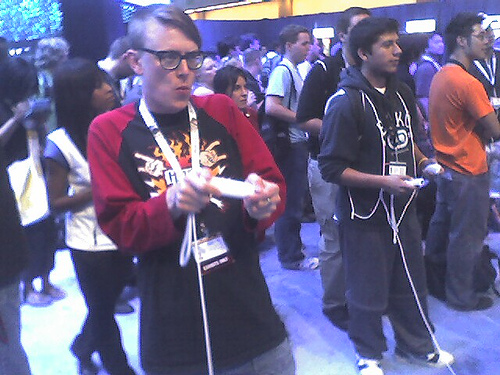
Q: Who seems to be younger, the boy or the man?
A: The boy is younger than the man.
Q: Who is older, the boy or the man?
A: The man is older than the boy.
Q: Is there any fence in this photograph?
A: No, there are no fences.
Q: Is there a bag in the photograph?
A: Yes, there is a bag.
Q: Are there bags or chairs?
A: Yes, there is a bag.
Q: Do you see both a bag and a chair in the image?
A: No, there is a bag but no chairs.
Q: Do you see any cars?
A: No, there are no cars.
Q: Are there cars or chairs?
A: No, there are no cars or chairs.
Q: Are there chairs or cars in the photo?
A: No, there are no cars or chairs.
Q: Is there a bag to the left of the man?
A: Yes, there is a bag to the left of the man.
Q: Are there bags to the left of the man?
A: Yes, there is a bag to the left of the man.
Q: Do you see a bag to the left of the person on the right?
A: Yes, there is a bag to the left of the man.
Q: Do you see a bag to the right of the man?
A: No, the bag is to the left of the man.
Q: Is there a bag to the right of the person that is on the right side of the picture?
A: No, the bag is to the left of the man.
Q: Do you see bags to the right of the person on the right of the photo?
A: No, the bag is to the left of the man.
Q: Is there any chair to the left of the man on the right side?
A: No, there is a bag to the left of the man.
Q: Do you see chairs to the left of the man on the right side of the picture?
A: No, there is a bag to the left of the man.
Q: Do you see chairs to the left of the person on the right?
A: No, there is a bag to the left of the man.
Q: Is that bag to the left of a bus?
A: No, the bag is to the left of a man.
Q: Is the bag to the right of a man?
A: No, the bag is to the left of a man.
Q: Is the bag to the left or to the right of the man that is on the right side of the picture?
A: The bag is to the left of the man.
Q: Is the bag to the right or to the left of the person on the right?
A: The bag is to the left of the man.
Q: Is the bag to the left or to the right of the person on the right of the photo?
A: The bag is to the left of the man.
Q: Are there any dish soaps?
A: No, there are no dish soaps.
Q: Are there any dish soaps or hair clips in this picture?
A: No, there are no dish soaps or hair clips.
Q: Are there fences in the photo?
A: No, there are no fences.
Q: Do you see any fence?
A: No, there are no fences.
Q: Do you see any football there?
A: No, there are no footballs.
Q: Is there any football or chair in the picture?
A: No, there are no footballs or chairs.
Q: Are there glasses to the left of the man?
A: Yes, there are glasses to the left of the man.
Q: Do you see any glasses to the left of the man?
A: Yes, there are glasses to the left of the man.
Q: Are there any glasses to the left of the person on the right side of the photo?
A: Yes, there are glasses to the left of the man.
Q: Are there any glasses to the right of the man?
A: No, the glasses are to the left of the man.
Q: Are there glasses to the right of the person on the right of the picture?
A: No, the glasses are to the left of the man.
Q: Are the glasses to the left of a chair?
A: No, the glasses are to the left of the man.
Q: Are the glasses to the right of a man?
A: No, the glasses are to the left of a man.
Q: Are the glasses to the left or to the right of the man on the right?
A: The glasses are to the left of the man.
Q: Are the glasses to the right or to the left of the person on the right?
A: The glasses are to the left of the man.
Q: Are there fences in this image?
A: No, there are no fences.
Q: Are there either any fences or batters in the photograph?
A: No, there are no fences or batters.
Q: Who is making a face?
A: The boy is making a face.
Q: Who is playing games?
A: The boy is playing games.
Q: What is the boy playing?
A: The boy is playing games.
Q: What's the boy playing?
A: The boy is playing games.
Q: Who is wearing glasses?
A: The boy is wearing glasses.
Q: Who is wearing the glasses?
A: The boy is wearing glasses.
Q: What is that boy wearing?
A: The boy is wearing glasses.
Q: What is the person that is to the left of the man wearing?
A: The boy is wearing glasses.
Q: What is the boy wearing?
A: The boy is wearing glasses.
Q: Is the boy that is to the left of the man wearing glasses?
A: Yes, the boy is wearing glasses.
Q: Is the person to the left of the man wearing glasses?
A: Yes, the boy is wearing glasses.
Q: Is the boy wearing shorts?
A: No, the boy is wearing glasses.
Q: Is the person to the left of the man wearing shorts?
A: No, the boy is wearing glasses.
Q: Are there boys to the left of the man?
A: Yes, there is a boy to the left of the man.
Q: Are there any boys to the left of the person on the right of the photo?
A: Yes, there is a boy to the left of the man.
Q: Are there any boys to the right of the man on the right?
A: No, the boy is to the left of the man.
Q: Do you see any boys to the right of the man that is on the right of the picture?
A: No, the boy is to the left of the man.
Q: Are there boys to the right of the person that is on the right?
A: No, the boy is to the left of the man.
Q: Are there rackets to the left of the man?
A: No, there is a boy to the left of the man.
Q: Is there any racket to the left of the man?
A: No, there is a boy to the left of the man.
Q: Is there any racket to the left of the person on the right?
A: No, there is a boy to the left of the man.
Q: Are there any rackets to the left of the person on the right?
A: No, there is a boy to the left of the man.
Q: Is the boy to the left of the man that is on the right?
A: Yes, the boy is to the left of the man.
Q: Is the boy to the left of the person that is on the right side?
A: Yes, the boy is to the left of the man.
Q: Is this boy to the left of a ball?
A: No, the boy is to the left of the man.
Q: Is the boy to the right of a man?
A: No, the boy is to the left of a man.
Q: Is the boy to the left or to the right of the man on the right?
A: The boy is to the left of the man.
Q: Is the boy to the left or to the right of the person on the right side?
A: The boy is to the left of the man.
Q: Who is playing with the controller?
A: The boy is playing with the controller.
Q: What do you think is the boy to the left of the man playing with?
A: The boy is playing with a controller.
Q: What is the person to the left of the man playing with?
A: The boy is playing with a controller.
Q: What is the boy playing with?
A: The boy is playing with a controller.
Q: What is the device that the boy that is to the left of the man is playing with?
A: The device is a controller.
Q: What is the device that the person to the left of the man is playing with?
A: The device is a controller.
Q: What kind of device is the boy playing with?
A: The boy is playing with a controller.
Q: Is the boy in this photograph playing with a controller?
A: Yes, the boy is playing with a controller.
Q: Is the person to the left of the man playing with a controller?
A: Yes, the boy is playing with a controller.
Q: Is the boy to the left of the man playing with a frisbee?
A: No, the boy is playing with a controller.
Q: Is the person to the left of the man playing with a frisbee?
A: No, the boy is playing with a controller.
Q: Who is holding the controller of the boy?
A: The boy is holding the controller.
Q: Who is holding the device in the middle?
A: The boy is holding the controller.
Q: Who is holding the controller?
A: The boy is holding the controller.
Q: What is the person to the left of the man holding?
A: The boy is holding the controller.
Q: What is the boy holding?
A: The boy is holding the controller.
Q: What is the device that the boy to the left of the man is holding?
A: The device is a controller.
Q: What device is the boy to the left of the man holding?
A: The boy is holding the controller.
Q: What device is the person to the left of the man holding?
A: The boy is holding the controller.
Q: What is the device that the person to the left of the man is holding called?
A: The device is a controller.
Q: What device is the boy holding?
A: The boy is holding the controller.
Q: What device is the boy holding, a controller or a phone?
A: The boy is holding a controller.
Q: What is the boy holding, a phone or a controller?
A: The boy is holding a controller.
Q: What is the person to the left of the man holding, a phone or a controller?
A: The boy is holding a controller.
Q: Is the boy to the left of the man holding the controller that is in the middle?
A: Yes, the boy is holding the controller.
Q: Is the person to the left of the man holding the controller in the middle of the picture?
A: Yes, the boy is holding the controller.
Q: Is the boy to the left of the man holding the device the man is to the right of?
A: Yes, the boy is holding the controller.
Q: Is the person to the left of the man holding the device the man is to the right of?
A: Yes, the boy is holding the controller.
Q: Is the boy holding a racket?
A: No, the boy is holding the controller.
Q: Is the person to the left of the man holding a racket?
A: No, the boy is holding the controller.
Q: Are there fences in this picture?
A: No, there are no fences.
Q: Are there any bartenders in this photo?
A: No, there are no bartenders.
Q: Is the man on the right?
A: Yes, the man is on the right of the image.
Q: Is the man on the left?
A: No, the man is on the right of the image.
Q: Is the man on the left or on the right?
A: The man is on the right of the image.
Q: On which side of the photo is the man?
A: The man is on the right of the image.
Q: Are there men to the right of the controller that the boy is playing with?
A: Yes, there is a man to the right of the controller.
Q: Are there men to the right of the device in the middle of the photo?
A: Yes, there is a man to the right of the controller.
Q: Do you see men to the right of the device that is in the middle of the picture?
A: Yes, there is a man to the right of the controller.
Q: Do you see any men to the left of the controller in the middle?
A: No, the man is to the right of the controller.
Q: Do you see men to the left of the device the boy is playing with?
A: No, the man is to the right of the controller.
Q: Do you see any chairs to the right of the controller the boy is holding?
A: No, there is a man to the right of the controller.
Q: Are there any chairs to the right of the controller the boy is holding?
A: No, there is a man to the right of the controller.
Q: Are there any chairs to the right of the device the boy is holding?
A: No, there is a man to the right of the controller.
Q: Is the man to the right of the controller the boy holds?
A: Yes, the man is to the right of the controller.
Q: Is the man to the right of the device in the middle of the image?
A: Yes, the man is to the right of the controller.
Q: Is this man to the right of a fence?
A: No, the man is to the right of the controller.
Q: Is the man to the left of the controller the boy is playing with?
A: No, the man is to the right of the controller.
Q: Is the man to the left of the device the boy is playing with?
A: No, the man is to the right of the controller.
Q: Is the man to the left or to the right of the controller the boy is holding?
A: The man is to the right of the controller.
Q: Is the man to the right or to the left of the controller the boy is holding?
A: The man is to the right of the controller.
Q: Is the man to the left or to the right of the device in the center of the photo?
A: The man is to the right of the controller.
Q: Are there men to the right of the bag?
A: Yes, there is a man to the right of the bag.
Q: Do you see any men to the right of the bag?
A: Yes, there is a man to the right of the bag.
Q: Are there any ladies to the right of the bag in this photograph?
A: No, there is a man to the right of the bag.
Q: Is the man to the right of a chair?
A: No, the man is to the right of the bag.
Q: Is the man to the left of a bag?
A: No, the man is to the right of a bag.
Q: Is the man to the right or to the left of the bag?
A: The man is to the right of the bag.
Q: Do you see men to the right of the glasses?
A: Yes, there is a man to the right of the glasses.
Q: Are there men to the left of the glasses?
A: No, the man is to the right of the glasses.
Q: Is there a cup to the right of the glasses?
A: No, there is a man to the right of the glasses.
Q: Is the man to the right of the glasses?
A: Yes, the man is to the right of the glasses.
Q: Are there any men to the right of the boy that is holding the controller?
A: Yes, there is a man to the right of the boy.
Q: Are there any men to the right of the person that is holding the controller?
A: Yes, there is a man to the right of the boy.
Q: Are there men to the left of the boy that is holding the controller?
A: No, the man is to the right of the boy.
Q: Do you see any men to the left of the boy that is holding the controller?
A: No, the man is to the right of the boy.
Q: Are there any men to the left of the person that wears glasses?
A: No, the man is to the right of the boy.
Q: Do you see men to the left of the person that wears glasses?
A: No, the man is to the right of the boy.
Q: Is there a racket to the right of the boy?
A: No, there is a man to the right of the boy.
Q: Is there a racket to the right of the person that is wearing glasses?
A: No, there is a man to the right of the boy.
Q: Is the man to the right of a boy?
A: Yes, the man is to the right of a boy.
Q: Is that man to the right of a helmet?
A: No, the man is to the right of a boy.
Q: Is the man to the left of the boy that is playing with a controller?
A: No, the man is to the right of the boy.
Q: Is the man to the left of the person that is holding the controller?
A: No, the man is to the right of the boy.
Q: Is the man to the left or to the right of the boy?
A: The man is to the right of the boy.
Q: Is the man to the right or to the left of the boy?
A: The man is to the right of the boy.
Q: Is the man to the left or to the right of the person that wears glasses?
A: The man is to the right of the boy.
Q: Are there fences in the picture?
A: No, there are no fences.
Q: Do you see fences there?
A: No, there are no fences.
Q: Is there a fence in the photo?
A: No, there are no fences.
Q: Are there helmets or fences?
A: No, there are no fences or helmets.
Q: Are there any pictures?
A: No, there are no pictures.